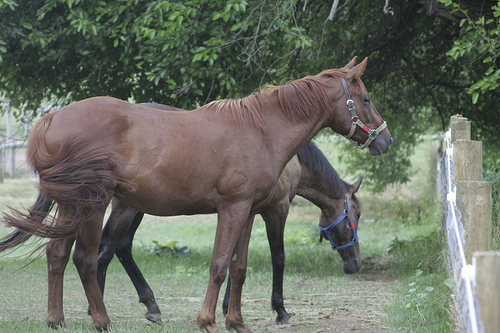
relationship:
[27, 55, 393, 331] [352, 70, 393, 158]
horse has face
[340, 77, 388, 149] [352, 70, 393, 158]
bridle on face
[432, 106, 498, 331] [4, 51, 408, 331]
fence in front of horses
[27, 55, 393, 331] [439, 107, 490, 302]
horse by fence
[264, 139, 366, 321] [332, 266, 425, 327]
horse by grass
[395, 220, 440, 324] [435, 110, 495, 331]
grass next to fence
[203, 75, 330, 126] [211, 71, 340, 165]
hair on neck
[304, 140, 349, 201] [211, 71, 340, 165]
hair on neck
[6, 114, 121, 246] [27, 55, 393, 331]
tail of horse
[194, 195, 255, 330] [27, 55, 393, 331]
leg of horse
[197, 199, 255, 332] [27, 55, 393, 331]
leg of horse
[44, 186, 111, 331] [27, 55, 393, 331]
back legs of horse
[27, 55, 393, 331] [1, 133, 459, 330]
horse standing on grass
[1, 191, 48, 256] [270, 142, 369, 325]
tail of horse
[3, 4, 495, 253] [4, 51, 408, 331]
trees near horses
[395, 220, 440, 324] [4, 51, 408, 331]
grass around horses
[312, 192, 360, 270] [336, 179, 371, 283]
harness on face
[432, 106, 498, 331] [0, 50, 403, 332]
fence in front of horse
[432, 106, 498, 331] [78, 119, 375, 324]
fence in front of horse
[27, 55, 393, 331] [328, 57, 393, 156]
horse has head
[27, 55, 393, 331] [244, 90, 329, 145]
horse has neck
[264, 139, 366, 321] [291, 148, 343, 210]
horse has neck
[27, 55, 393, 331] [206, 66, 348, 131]
horse has hair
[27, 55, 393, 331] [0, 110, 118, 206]
horse has tail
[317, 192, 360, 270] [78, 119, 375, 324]
harness on horse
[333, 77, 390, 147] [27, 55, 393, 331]
bridle on horse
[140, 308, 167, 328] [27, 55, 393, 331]
hoof on horse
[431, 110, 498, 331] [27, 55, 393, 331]
stone wall bounds horse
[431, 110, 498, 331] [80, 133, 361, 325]
stone wall bounds horse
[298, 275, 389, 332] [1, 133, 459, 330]
dirt patch has grass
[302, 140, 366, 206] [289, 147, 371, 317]
mane on horse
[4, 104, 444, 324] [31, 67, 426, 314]
ground near horses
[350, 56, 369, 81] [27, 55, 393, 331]
ear of horse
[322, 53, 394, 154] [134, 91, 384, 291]
head of horse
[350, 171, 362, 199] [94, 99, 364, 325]
ear of horse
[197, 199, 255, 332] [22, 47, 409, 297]
leg of horse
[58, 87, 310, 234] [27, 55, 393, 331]
body of horse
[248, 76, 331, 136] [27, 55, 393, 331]
mane of horse